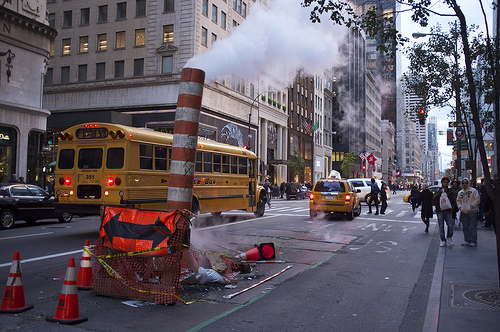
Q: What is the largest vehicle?
A: The Bus.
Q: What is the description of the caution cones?
A: Orange with stripes.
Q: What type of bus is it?
A: A school bus.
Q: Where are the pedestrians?
A: On the sidewalk.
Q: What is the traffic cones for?
A: To indicate road hazard.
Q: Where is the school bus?
A: At the intersection.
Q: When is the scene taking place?
A: At daytime.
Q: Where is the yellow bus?
A: On the road.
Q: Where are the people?
A: In the city.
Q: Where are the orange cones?
A: On the ground.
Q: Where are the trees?
A: On the sidewalk.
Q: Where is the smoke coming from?
A: The orange and white tube.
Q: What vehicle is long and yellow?
A: The school bus.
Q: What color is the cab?
A: Yellow.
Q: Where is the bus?
A: The street.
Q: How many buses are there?
A: One.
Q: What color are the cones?
A: Orange.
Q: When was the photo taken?
A: Day time.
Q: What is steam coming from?
A: The pole.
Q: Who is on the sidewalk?
A: Pedestrians.